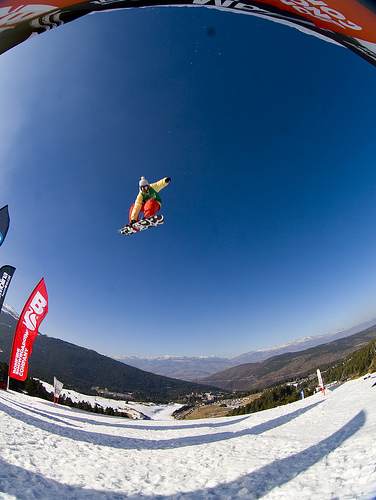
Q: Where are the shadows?
A: On the snow.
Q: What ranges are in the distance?
A: Mountain.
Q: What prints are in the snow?
A: Footprints.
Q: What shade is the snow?
A: White.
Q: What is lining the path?
A: Trees.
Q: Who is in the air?
A: Snowboarder.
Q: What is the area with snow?
A: A snow slope.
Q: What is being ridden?
A: Snowboard.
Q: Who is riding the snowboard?
A: The man.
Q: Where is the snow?
A: On mountains.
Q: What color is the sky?
A: Blue.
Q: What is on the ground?
A: Snow.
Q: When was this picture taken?
A: Daytime.